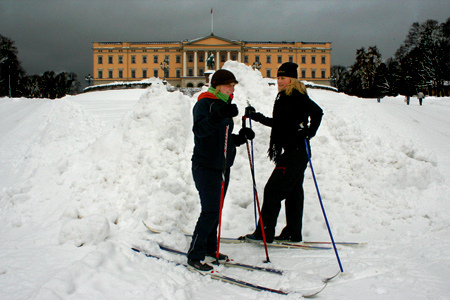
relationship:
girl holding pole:
[186, 69, 254, 272] [216, 182, 224, 214]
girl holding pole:
[244, 62, 326, 242] [302, 140, 348, 277]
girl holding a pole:
[244, 62, 326, 242] [302, 140, 348, 277]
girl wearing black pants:
[244, 62, 326, 242] [254, 160, 310, 233]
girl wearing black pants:
[186, 69, 254, 272] [185, 162, 230, 258]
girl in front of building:
[181, 68, 255, 271] [90, 7, 334, 94]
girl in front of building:
[244, 61, 325, 242] [90, 7, 334, 94]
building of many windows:
[90, 7, 334, 94] [320, 69, 325, 78]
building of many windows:
[90, 7, 334, 94] [310, 68, 315, 77]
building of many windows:
[90, 7, 334, 94] [321, 56, 326, 63]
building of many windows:
[90, 7, 334, 94] [301, 56, 306, 64]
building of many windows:
[90, 7, 334, 94] [265, 55, 270, 62]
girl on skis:
[244, 62, 326, 242] [153, 239, 369, 290]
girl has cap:
[186, 69, 254, 272] [209, 66, 241, 88]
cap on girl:
[209, 66, 241, 88] [186, 69, 254, 272]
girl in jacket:
[244, 62, 326, 242] [248, 85, 325, 160]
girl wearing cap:
[186, 69, 254, 272] [211, 69, 238, 88]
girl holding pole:
[186, 69, 254, 272] [243, 118, 272, 264]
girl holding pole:
[186, 69, 254, 272] [211, 121, 232, 267]